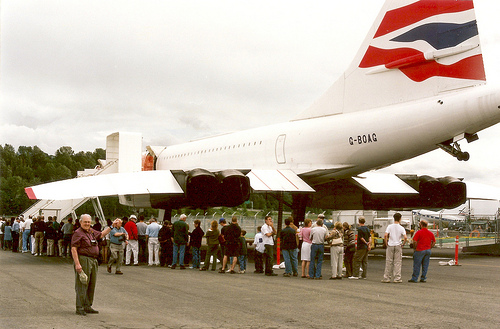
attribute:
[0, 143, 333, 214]
trees — part, some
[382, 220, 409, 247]
top — part, white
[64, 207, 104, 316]
man — pointing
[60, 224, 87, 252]
short sleeve — white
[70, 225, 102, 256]
shirt — part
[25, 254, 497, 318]
runway — part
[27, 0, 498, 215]
airplane — white, red, blue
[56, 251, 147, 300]
green trouser — part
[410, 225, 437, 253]
shirt — red